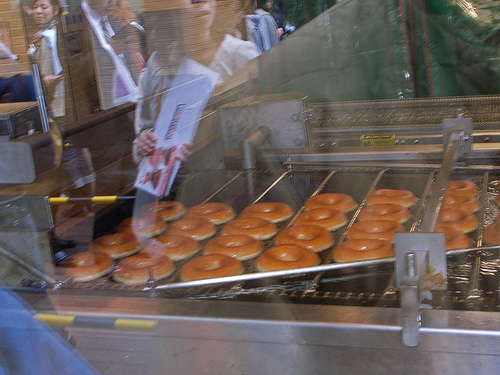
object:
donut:
[201, 230, 264, 262]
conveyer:
[3, 169, 500, 304]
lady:
[132, 0, 263, 181]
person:
[26, 0, 68, 118]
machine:
[0, 96, 499, 375]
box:
[0, 100, 44, 141]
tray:
[50, 192, 499, 282]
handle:
[32, 312, 159, 330]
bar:
[0, 0, 497, 372]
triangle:
[112, 70, 132, 100]